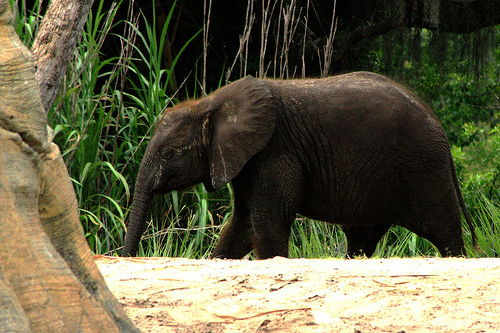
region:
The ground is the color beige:
[167, 267, 459, 321]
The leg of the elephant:
[239, 186, 290, 258]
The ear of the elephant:
[207, 76, 282, 191]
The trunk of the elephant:
[118, 173, 154, 261]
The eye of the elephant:
[154, 138, 180, 165]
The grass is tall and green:
[66, 88, 130, 189]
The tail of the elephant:
[443, 125, 478, 258]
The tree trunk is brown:
[28, 3, 78, 105]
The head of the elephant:
[118, 95, 210, 260]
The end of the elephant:
[328, 66, 481, 256]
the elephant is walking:
[45, 35, 492, 261]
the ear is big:
[172, 58, 296, 186]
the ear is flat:
[198, 53, 280, 208]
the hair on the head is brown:
[142, 90, 218, 127]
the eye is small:
[137, 132, 192, 167]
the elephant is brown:
[107, 39, 481, 238]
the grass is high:
[90, 186, 498, 258]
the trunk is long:
[106, 137, 177, 260]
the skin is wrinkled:
[251, 80, 346, 181]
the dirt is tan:
[138, 255, 462, 327]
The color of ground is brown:
[165, 267, 428, 312]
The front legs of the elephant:
[207, 185, 303, 265]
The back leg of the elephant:
[330, 225, 390, 260]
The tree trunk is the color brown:
[5, 45, 95, 325]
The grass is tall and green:
[440, 71, 495, 233]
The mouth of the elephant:
[146, 171, 190, 201]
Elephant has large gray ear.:
[207, 97, 275, 169]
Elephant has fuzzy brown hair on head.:
[156, 97, 208, 119]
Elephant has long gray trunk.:
[113, 153, 169, 276]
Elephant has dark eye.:
[158, 142, 185, 174]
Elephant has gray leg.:
[244, 181, 319, 283]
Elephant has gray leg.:
[206, 200, 256, 262]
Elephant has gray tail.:
[448, 136, 478, 249]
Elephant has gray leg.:
[329, 203, 380, 253]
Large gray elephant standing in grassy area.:
[136, 45, 476, 256]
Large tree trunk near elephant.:
[2, 55, 112, 332]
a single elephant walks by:
[108, 70, 491, 253]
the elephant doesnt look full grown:
[123, 83, 485, 273]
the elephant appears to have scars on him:
[146, 81, 292, 210]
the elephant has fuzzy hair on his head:
[144, 95, 251, 131]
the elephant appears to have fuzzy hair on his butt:
[342, 56, 487, 249]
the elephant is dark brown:
[89, 40, 498, 252]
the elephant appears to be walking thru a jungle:
[45, 14, 487, 180]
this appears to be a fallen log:
[142, 254, 467, 328]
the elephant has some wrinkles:
[131, 91, 458, 207]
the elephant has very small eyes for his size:
[140, 126, 189, 183]